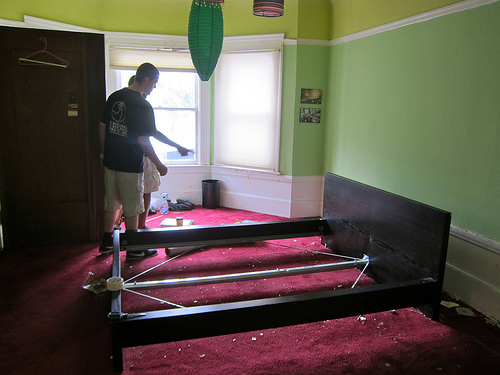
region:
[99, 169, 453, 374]
brown wooden bed frame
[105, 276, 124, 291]
roll of clear tape sitting on bed frame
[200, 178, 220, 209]
black cylinder waste basket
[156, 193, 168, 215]
bottle of spray cleaner on the floor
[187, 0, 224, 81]
green decoration hanging from ceiling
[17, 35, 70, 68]
clothes hangers hanging from door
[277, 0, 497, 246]
light green paint on middle part of wall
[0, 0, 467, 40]
mustard yellow paint on top part of wall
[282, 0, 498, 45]
white molding between middle and top wall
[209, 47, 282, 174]
white window shade pulled down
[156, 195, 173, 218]
bottle of windex on the floor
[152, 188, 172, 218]
glass cleaner on the floor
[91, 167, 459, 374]
bed on the floor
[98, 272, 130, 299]
roll of tape on the bed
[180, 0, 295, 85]
light fixtures hanging from ceiling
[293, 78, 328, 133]
pictures on the green wall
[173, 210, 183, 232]
coffee cup on the floor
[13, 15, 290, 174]
bay windows on the wall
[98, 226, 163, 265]
nike athletic trainers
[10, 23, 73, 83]
clothes hanger hanging from the door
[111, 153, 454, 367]
Wooden bed frame without mattress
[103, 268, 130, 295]
Roll of packing tape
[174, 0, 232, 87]
Decorative light hanging from ceiling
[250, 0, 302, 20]
decorative light from ceiling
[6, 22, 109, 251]
bedroom wardrobe that is empty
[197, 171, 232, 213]
Trashcan to collect debris from moving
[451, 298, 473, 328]
Random CD and CD case on floor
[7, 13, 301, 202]
Eclectic bay window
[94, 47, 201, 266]
Two individuals planning on disassembling bed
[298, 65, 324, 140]
Two random pictures on green wall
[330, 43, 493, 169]
a wall painted green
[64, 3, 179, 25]
wall painted yellow green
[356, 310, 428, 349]
red carpet with dirt on it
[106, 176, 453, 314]
a dark wood bed frame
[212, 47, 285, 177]
window with the blind pulled down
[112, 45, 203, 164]
window with the blind pulled up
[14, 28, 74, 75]
an empty clothes hanger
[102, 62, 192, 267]
two men standing in a room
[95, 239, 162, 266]
black nike shoes with white logo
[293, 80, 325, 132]
two small pictures hung on the wall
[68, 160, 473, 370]
wood and metal bed frame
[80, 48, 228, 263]
two men in shorts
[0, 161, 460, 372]
red shag carpet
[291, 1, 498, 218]
two-tone green painted wall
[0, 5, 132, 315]
wood dressing cabinet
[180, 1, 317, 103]
paper lights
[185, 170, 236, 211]
trash can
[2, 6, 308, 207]
bay window in a house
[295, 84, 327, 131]
small paintings on a green wall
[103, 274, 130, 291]
clear shipping tape sitting atop bed frame